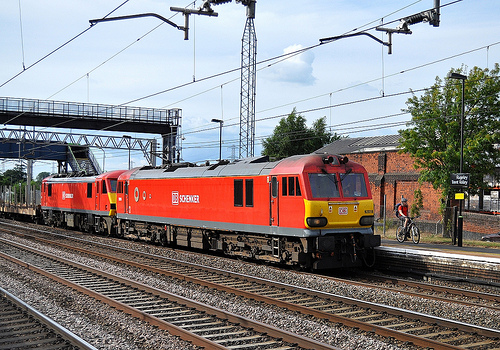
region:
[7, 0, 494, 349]
A busy train station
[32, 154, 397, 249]
Two red trains going to where ever.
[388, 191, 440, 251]
A biker in a red shirt goes about his day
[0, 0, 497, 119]
Powerlines high above their heads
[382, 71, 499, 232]
Tree is adjacent to the train track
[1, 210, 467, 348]
Four train tracks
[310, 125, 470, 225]
A red brick building in the background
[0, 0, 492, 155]
Clear cloudy blue sky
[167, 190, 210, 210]
A prominantly displayed white logo on the train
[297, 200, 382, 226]
The yellow front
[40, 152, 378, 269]
A short red train at a platform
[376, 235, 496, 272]
Railway platform near the train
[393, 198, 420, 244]
One cyclist on the railway platform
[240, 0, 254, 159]
Pillar supporting the overhead power cables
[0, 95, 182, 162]
One overhead bridge across the rail tracks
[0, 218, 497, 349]
The rails on the gravel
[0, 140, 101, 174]
Another overhead bridge with stairs to land on the platform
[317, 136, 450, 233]
A shade with red brick walls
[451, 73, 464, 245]
One light and light pole on the platform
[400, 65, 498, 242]
A green tree near the cyclist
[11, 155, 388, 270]
the train is red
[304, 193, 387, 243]
front of train is yellow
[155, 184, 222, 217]
white letters on train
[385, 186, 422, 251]
person riding a bicycle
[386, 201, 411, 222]
person's shirt is red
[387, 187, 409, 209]
person wearing a helmet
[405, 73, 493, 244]
tree near the bicycler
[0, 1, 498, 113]
metal structure above the train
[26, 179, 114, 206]
black windows on train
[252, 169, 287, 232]
train door is red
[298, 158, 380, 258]
the front of train is red and yellow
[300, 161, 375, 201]
wipes on windshield of train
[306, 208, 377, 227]
headlights of train on yellow background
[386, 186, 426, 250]
a man biking on side a platform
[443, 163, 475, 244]
a sign on a pole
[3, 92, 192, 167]
two bridges over the railroad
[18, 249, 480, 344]
rails are covered with gravel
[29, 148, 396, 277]
train has two carts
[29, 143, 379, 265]
carts of train are red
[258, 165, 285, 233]
a red door of train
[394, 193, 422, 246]
man in a red shirt on a bicycle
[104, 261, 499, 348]
3 complete sets of train tracks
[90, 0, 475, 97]
overhead power wires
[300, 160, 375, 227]
the front of the train is red and yellow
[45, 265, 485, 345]
gravel between and underneath the railroad tracks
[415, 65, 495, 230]
a leafy green tree behind the black pole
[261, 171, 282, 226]
the train front door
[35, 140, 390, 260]
there are 2 matching railroad trains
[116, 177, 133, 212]
back door of the train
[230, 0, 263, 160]
a tall power tower